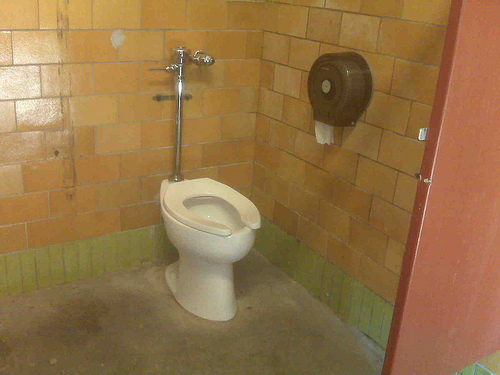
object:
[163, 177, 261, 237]
toilet plate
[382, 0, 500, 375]
door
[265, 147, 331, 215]
ground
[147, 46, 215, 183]
pipe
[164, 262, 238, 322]
base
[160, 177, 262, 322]
toilet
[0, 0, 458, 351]
grout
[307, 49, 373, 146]
toilet paper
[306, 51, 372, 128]
dispenser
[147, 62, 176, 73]
handle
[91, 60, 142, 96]
wall tile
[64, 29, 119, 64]
wall tile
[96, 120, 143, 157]
wall tile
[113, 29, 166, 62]
wall tile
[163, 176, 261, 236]
seat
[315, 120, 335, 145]
tissue paper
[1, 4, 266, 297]
wall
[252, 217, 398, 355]
bottom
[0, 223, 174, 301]
bottom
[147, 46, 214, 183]
water pump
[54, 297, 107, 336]
stain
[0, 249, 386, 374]
floor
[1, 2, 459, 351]
tile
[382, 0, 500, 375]
bathroom stahl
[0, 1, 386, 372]
bathroom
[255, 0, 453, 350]
wall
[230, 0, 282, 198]
corner